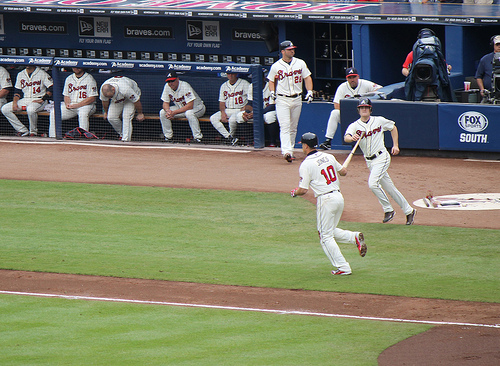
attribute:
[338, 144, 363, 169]
baseball bat — light, beige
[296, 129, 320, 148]
helmet — black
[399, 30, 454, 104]
camera — TV camera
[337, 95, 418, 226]
player — running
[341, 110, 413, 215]
uniform — white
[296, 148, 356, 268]
uniform — white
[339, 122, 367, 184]
bat — wooden , baseball bat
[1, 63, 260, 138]
baseball players — sitting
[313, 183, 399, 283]
pants — long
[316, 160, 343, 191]
number — red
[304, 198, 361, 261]
pants — white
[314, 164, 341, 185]
number — 10, red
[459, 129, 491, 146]
south — white, word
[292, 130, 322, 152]
baseball helmet — blue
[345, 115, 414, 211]
uniform — white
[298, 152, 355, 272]
uniform — white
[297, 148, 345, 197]
shirt — short sleeved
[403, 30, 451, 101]
cloth — blue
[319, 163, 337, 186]
number — 10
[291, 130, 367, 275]
player — running